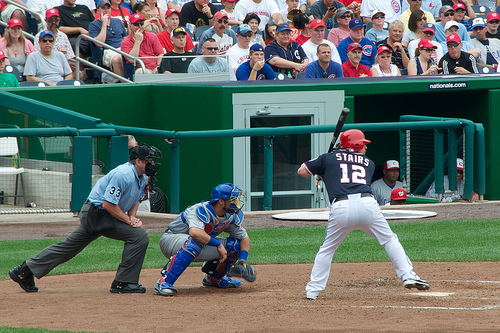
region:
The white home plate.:
[405, 284, 458, 300]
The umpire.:
[154, 179, 259, 293]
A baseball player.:
[289, 98, 431, 304]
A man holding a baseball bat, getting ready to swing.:
[297, 101, 434, 301]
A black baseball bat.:
[324, 105, 349, 154]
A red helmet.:
[340, 125, 371, 150]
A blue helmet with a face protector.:
[211, 179, 245, 213]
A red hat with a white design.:
[389, 187, 409, 200]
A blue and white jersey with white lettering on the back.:
[302, 147, 380, 196]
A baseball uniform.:
[301, 147, 424, 289]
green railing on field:
[167, 115, 457, 140]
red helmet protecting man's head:
[335, 125, 381, 149]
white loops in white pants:
[326, 185, 386, 204]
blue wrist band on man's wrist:
[198, 237, 238, 248]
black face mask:
[144, 147, 178, 197]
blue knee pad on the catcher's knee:
[156, 239, 216, 290]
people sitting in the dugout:
[346, 110, 472, 225]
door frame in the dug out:
[225, 91, 343, 213]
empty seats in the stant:
[19, 72, 109, 98]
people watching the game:
[248, 12, 435, 82]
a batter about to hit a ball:
[283, 90, 458, 314]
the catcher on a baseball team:
[156, 169, 269, 293]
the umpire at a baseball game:
[1, 121, 166, 298]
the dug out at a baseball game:
[356, 98, 491, 203]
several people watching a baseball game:
[215, 3, 475, 75]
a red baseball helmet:
[334, 124, 371, 159]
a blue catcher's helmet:
[198, 175, 250, 217]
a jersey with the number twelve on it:
[302, 146, 386, 203]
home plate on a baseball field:
[399, 282, 455, 306]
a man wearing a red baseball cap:
[341, 37, 368, 67]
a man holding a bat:
[287, 102, 419, 299]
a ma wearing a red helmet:
[331, 124, 378, 161]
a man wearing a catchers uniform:
[161, 183, 266, 305]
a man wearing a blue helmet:
[208, 180, 255, 215]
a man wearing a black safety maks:
[124, 134, 161, 199]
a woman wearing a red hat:
[3, 14, 26, 38]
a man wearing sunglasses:
[33, 29, 63, 54]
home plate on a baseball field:
[394, 267, 481, 331]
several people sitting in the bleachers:
[126, 8, 476, 69]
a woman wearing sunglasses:
[416, 39, 436, 62]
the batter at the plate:
[273, 107, 441, 305]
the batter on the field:
[290, 99, 440, 328]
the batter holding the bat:
[289, 95, 453, 306]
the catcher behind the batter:
[147, 183, 289, 302]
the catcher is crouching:
[146, 164, 273, 308]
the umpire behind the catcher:
[46, 131, 163, 300]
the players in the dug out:
[379, 145, 496, 200]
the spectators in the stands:
[18, 8, 491, 78]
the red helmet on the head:
[326, 122, 381, 150]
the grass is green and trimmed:
[417, 223, 498, 257]